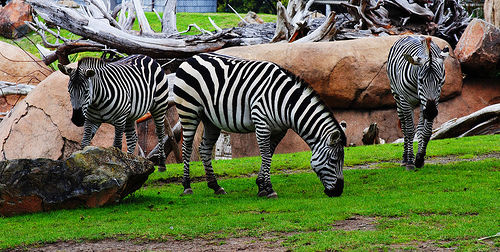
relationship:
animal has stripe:
[152, 53, 346, 205] [58, 52, 347, 147]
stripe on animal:
[58, 52, 347, 147] [162, 64, 302, 129]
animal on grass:
[58, 52, 347, 198] [3, 134, 485, 250]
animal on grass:
[386, 35, 449, 170] [384, 165, 457, 222]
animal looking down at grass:
[58, 52, 347, 198] [3, 134, 485, 250]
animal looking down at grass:
[386, 35, 449, 170] [3, 134, 485, 250]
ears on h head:
[403, 45, 450, 65] [404, 47, 454, 120]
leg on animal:
[255, 125, 272, 183] [58, 52, 347, 198]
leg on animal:
[256, 125, 289, 197] [58, 52, 347, 198]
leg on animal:
[177, 111, 197, 193] [58, 52, 347, 198]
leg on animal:
[197, 112, 225, 193] [58, 52, 347, 198]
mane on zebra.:
[304, 76, 318, 96] [360, 24, 482, 214]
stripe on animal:
[58, 52, 347, 147] [172, 43, 375, 209]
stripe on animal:
[58, 52, 347, 147] [65, 53, 195, 148]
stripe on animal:
[58, 52, 347, 147] [376, 29, 477, 194]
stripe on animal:
[175, 67, 215, 119] [55, 53, 167, 170]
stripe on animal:
[58, 52, 347, 147] [172, 50, 346, 195]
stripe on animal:
[175, 67, 215, 119] [385, 33, 450, 168]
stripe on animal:
[58, 52, 347, 147] [385, 33, 450, 168]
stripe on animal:
[58, 52, 347, 147] [132, 25, 414, 209]